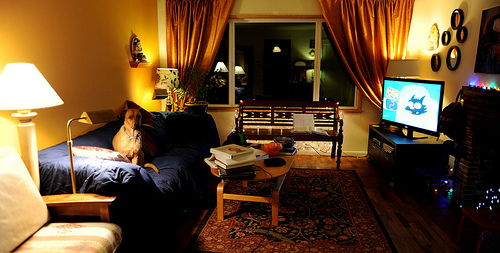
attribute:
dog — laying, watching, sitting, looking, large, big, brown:
[112, 101, 158, 179]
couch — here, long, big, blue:
[144, 114, 200, 208]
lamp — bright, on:
[3, 61, 66, 185]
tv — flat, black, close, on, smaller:
[363, 67, 461, 148]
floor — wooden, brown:
[300, 148, 389, 210]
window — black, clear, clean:
[238, 24, 323, 96]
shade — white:
[0, 60, 60, 110]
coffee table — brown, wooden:
[221, 133, 286, 225]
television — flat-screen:
[378, 77, 442, 136]